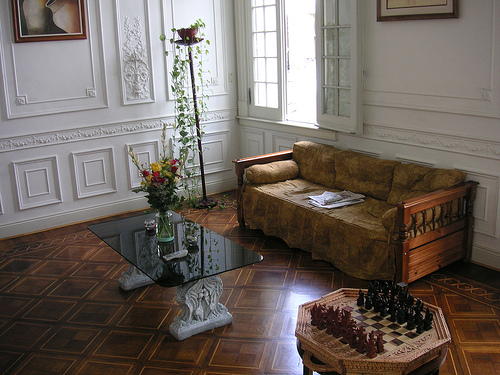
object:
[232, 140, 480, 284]
couch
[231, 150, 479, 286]
couch frame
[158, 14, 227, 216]
plant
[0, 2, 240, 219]
wall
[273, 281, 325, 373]
light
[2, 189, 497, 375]
floor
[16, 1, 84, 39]
picture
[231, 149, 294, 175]
arm rest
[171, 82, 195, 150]
leaves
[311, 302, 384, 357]
chess pieces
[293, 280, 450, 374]
chess table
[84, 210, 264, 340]
coffee table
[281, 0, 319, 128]
opened window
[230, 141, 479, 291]
upholstery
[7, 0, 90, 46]
frame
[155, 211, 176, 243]
vase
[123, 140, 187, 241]
bouquet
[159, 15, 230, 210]
plant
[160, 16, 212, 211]
vines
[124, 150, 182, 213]
flowers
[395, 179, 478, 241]
arm rest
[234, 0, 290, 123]
shutter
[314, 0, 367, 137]
shutter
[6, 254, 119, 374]
tiles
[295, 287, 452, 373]
chess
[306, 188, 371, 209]
white papers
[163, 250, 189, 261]
controller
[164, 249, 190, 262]
remote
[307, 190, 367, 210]
paper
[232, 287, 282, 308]
square pattern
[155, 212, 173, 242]
glass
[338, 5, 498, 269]
wall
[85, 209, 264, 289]
top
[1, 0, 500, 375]
living room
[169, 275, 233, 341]
base